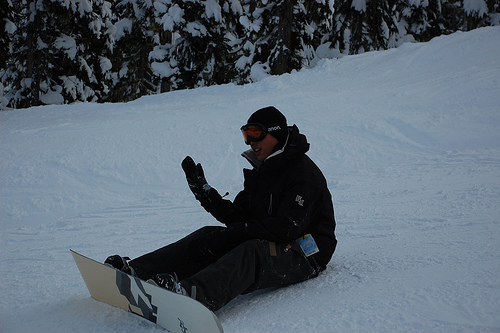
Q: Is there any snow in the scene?
A: Yes, there is snow.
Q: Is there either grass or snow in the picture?
A: Yes, there is snow.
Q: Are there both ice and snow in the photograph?
A: No, there is snow but no ice.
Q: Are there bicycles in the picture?
A: No, there are no bicycles.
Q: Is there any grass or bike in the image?
A: No, there are no bikes or grass.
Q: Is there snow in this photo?
A: Yes, there is snow.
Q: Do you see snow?
A: Yes, there is snow.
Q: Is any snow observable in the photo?
A: Yes, there is snow.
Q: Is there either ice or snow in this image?
A: Yes, there is snow.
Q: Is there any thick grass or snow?
A: Yes, there is thick snow.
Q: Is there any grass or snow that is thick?
A: Yes, the snow is thick.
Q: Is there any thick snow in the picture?
A: Yes, there is thick snow.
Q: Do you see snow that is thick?
A: Yes, there is snow that is thick.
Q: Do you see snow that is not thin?
A: Yes, there is thick snow.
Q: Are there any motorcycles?
A: No, there are no motorcycles.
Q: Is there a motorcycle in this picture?
A: No, there are no motorcycles.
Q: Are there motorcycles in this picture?
A: No, there are no motorcycles.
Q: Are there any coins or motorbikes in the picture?
A: No, there are no motorbikes or coins.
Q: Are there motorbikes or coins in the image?
A: No, there are no motorbikes or coins.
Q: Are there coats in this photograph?
A: Yes, there is a coat.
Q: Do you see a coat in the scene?
A: Yes, there is a coat.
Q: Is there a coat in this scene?
A: Yes, there is a coat.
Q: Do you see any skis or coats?
A: Yes, there is a coat.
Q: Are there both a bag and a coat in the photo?
A: No, there is a coat but no bags.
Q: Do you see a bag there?
A: No, there are no bags.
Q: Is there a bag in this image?
A: No, there are no bags.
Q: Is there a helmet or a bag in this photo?
A: No, there are no bags or helmets.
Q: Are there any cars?
A: No, there are no cars.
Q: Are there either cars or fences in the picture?
A: No, there are no cars or fences.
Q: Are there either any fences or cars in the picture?
A: No, there are no cars or fences.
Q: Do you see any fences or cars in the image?
A: No, there are no cars or fences.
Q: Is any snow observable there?
A: Yes, there is snow.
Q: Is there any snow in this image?
A: Yes, there is snow.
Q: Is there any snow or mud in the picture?
A: Yes, there is snow.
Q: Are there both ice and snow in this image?
A: No, there is snow but no ice.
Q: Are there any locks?
A: No, there are no locks.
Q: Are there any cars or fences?
A: No, there are no fences or cars.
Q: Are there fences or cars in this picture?
A: No, there are no fences or cars.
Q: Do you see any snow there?
A: Yes, there is snow.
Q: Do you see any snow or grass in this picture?
A: Yes, there is snow.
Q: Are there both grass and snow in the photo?
A: No, there is snow but no grass.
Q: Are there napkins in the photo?
A: No, there are no napkins.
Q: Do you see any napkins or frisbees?
A: No, there are no napkins or frisbees.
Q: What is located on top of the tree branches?
A: The snow is on top of the tree branches.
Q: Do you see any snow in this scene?
A: Yes, there is snow.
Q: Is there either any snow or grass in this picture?
A: Yes, there is snow.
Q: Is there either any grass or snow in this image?
A: Yes, there is snow.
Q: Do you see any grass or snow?
A: Yes, there is snow.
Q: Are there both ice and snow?
A: No, there is snow but no ice.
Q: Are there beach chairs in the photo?
A: No, there are no beach chairs.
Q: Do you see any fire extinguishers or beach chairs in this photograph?
A: No, there are no beach chairs or fire extinguishers.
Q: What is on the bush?
A: The snow is on the bush.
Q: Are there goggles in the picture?
A: Yes, there are goggles.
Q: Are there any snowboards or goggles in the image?
A: Yes, there are goggles.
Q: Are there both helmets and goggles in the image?
A: No, there are goggles but no helmets.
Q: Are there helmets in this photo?
A: No, there are no helmets.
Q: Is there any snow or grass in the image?
A: Yes, there is snow.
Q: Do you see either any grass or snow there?
A: Yes, there is snow.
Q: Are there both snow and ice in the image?
A: No, there is snow but no ice.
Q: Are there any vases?
A: No, there are no vases.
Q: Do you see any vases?
A: No, there are no vases.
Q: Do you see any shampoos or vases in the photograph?
A: No, there are no vases or shampoos.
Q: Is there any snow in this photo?
A: Yes, there is snow.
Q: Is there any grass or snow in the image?
A: Yes, there is snow.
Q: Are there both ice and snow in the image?
A: No, there is snow but no ice.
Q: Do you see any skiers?
A: No, there are no skiers.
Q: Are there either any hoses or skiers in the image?
A: No, there are no skiers or hoses.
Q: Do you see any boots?
A: Yes, there are boots.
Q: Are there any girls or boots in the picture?
A: Yes, there are boots.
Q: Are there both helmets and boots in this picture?
A: No, there are boots but no helmets.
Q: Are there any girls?
A: No, there are no girls.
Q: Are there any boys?
A: No, there are no boys.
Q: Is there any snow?
A: Yes, there is snow.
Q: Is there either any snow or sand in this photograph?
A: Yes, there is snow.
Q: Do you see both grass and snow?
A: No, there is snow but no grass.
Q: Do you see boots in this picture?
A: Yes, there are boots.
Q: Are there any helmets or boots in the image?
A: Yes, there are boots.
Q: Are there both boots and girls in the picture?
A: No, there are boots but no girls.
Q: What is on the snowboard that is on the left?
A: The boots are on the snow board.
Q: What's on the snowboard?
A: The boots are on the snow board.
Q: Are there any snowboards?
A: Yes, there is a snowboard.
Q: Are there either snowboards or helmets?
A: Yes, there is a snowboard.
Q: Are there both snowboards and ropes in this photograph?
A: No, there is a snowboard but no ropes.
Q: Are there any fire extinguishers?
A: No, there are no fire extinguishers.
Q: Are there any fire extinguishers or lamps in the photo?
A: No, there are no fire extinguishers or lamps.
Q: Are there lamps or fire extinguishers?
A: No, there are no fire extinguishers or lamps.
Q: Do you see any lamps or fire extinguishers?
A: No, there are no fire extinguishers or lamps.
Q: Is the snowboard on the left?
A: Yes, the snowboard is on the left of the image.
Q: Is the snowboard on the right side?
A: No, the snowboard is on the left of the image.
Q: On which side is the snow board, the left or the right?
A: The snow board is on the left of the image.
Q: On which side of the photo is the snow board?
A: The snow board is on the left of the image.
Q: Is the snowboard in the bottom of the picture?
A: Yes, the snowboard is in the bottom of the image.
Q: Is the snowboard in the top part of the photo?
A: No, the snowboard is in the bottom of the image.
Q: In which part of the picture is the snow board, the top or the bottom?
A: The snow board is in the bottom of the image.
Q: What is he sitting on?
A: The guy is sitting on the snow.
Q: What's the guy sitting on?
A: The guy is sitting on the snow.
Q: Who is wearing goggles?
A: The guy is wearing goggles.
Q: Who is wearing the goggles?
A: The guy is wearing goggles.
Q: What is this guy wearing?
A: The guy is wearing goggles.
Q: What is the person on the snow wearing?
A: The guy is wearing goggles.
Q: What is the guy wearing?
A: The guy is wearing goggles.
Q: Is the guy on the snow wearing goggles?
A: Yes, the guy is wearing goggles.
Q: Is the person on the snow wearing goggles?
A: Yes, the guy is wearing goggles.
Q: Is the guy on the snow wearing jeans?
A: No, the guy is wearing goggles.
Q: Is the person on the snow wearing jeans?
A: No, the guy is wearing goggles.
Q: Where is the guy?
A: The guy is on the snow.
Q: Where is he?
A: The guy is on the snow.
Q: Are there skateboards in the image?
A: No, there are no skateboards.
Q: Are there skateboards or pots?
A: No, there are no skateboards or pots.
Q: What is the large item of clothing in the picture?
A: The clothing item is a snowsuit.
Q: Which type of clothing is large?
A: The clothing is a snowsuit.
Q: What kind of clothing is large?
A: The clothing is a snowsuit.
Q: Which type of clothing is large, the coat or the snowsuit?
A: The snowsuit is large.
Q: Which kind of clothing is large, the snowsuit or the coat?
A: The snowsuit is large.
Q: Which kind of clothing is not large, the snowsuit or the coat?
A: The coat is not large.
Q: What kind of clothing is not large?
A: The clothing is a coat.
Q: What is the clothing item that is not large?
A: The clothing item is a coat.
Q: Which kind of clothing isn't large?
A: The clothing is a coat.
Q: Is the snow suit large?
A: Yes, the snow suit is large.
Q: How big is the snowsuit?
A: The snowsuit is large.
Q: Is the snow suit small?
A: No, the snow suit is large.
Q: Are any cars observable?
A: No, there are no cars.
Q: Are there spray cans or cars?
A: No, there are no cars or spray cans.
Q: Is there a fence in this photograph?
A: No, there are no fences.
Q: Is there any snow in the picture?
A: Yes, there is snow.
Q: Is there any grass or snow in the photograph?
A: Yes, there is snow.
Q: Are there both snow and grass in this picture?
A: No, there is snow but no grass.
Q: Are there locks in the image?
A: No, there are no locks.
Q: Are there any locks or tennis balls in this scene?
A: No, there are no locks or tennis balls.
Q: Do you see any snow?
A: Yes, there is snow.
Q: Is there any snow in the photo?
A: Yes, there is snow.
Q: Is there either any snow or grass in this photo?
A: Yes, there is snow.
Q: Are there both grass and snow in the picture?
A: No, there is snow but no grass.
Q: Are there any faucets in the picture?
A: No, there are no faucets.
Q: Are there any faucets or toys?
A: No, there are no faucets or toys.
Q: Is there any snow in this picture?
A: Yes, there is snow.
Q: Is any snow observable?
A: Yes, there is snow.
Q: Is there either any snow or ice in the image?
A: Yes, there is snow.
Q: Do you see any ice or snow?
A: Yes, there is snow.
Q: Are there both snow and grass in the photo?
A: No, there is snow but no grass.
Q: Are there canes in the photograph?
A: No, there are no canes.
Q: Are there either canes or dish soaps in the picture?
A: No, there are no canes or dish soaps.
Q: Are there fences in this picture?
A: No, there are no fences.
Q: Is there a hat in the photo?
A: Yes, there is a hat.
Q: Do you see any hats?
A: Yes, there is a hat.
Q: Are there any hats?
A: Yes, there is a hat.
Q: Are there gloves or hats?
A: Yes, there is a hat.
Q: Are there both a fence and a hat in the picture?
A: No, there is a hat but no fences.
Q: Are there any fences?
A: No, there are no fences.